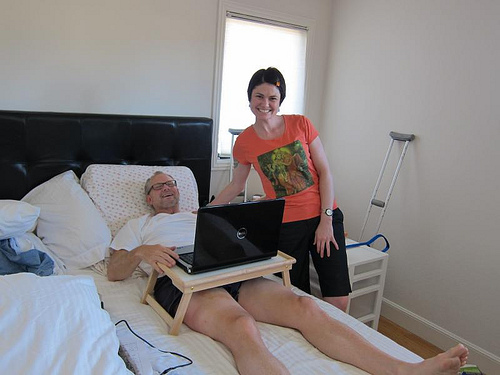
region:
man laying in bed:
[87, 139, 447, 374]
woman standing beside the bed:
[194, 62, 399, 326]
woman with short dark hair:
[201, 53, 397, 309]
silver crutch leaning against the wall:
[348, 108, 425, 263]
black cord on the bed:
[110, 313, 185, 373]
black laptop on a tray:
[143, 202, 308, 339]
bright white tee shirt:
[104, 202, 221, 266]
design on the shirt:
[252, 147, 323, 208]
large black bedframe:
[1, 102, 218, 215]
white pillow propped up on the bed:
[22, 177, 108, 266]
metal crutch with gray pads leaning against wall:
[355, 125, 421, 330]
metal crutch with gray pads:
[221, 115, 265, 312]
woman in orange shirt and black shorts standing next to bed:
[186, 64, 355, 348]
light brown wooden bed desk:
[140, 233, 308, 338]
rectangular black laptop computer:
[155, 189, 292, 278]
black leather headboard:
[1, 103, 229, 275]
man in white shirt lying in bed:
[103, 169, 480, 374]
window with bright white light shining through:
[209, 0, 313, 175]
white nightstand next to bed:
[215, 191, 393, 346]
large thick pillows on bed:
[1, 157, 208, 272]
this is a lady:
[233, 73, 323, 188]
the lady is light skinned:
[263, 111, 280, 123]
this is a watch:
[321, 208, 336, 219]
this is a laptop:
[197, 208, 261, 255]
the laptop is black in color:
[202, 218, 229, 254]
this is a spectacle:
[137, 180, 185, 187]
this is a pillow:
[101, 171, 131, 195]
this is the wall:
[373, 26, 448, 81]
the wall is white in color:
[429, 174, 481, 253]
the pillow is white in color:
[58, 188, 75, 259]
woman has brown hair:
[249, 71, 285, 104]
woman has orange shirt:
[252, 119, 317, 211]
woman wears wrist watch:
[314, 209, 332, 228]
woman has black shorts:
[299, 217, 361, 300]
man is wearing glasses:
[152, 178, 192, 203]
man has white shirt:
[129, 201, 216, 266]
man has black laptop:
[189, 192, 289, 280]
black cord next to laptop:
[107, 286, 187, 363]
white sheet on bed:
[70, 223, 170, 350]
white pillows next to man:
[30, 181, 127, 269]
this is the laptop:
[178, 190, 287, 270]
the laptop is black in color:
[193, 190, 282, 265]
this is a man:
[136, 165, 182, 236]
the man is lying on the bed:
[132, 166, 183, 230]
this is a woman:
[226, 65, 336, 199]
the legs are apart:
[263, 310, 325, 373]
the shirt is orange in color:
[291, 119, 309, 138]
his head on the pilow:
[92, 169, 137, 219]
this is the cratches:
[368, 127, 421, 206]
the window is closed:
[248, 22, 288, 54]